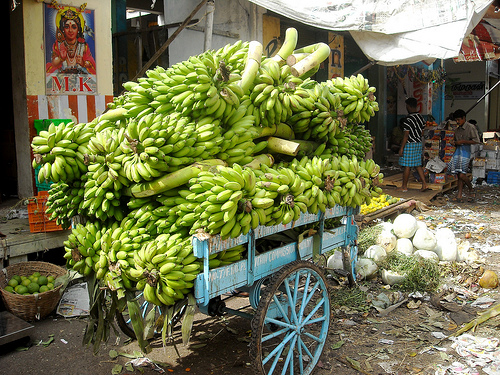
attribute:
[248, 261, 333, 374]
wheel — blue, large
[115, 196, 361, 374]
cart — blue, light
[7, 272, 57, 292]
limes — green, fruit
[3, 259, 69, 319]
basket — brown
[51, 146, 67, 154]
banana — unripe, green, yellow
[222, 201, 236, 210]
banana — green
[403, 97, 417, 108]
cap — black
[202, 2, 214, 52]
pole — white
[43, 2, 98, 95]
poster — colorful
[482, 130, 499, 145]
box — opened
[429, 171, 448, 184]
crate — wooden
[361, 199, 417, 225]
wood — long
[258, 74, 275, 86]
banana — green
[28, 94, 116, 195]
wall — red, white, striped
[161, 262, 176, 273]
banana — yellow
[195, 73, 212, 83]
banana — green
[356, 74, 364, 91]
banana — yellow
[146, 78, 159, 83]
banana — green